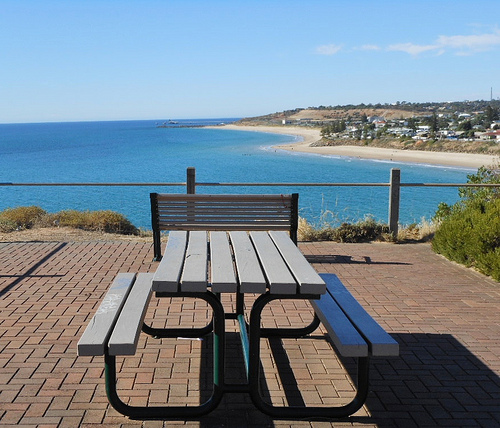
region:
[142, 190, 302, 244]
The bench facing the water.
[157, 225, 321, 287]
The table top of the picnic table.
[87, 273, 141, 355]
The left bench seat of the picnic table.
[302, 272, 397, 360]
The right bench seat of the picnic table.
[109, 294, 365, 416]
The pipes under the picnic table.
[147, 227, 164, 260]
The left leg of the bench.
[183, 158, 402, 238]
The wooden post in front of the bench.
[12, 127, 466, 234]
The water in front of the bench.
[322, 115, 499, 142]
The houses on the right.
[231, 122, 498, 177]
The sand area of the beach.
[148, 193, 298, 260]
wood and metal bench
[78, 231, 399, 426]
wood and metal picnic table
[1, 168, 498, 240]
brown wood fence posts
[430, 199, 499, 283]
green bushes by patio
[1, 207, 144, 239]
green bushes on hill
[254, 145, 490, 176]
wave breaking on shore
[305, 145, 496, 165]
white sand on beach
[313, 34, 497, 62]
white clouds in sky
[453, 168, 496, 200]
tree with green leaves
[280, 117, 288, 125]
white building by beach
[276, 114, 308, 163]
Water washing up on shore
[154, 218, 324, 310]
Gray table on the balcony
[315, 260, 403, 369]
Gray bench on the balcony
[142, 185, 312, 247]
Park Bench on the balcony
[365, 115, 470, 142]
House on the beach front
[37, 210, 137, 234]
Bushes on the ledge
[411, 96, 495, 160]
City view in the distance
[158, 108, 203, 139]
Rocks in the water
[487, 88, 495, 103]
cellphone tower in the city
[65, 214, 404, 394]
Bench and chairs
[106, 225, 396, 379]
A table and bench on the brick floor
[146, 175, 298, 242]
A bench facing view of the ocean.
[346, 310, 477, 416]
Shadow of the bench on ground.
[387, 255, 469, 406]
The ground is made of bricks.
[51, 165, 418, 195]
A rod facing the bench.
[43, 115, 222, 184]
A beautiful beach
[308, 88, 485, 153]
A town sits in the background.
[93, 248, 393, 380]
Two benches and a table.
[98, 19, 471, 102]
The sky has a few clouds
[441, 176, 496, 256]
Bushes growing on the side.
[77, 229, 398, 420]
picnic table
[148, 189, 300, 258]
wood and metal bench overlooking the water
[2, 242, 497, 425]
brick patio with a picnic table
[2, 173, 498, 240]
wood railing by the patio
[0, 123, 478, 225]
clear blue water below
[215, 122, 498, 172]
white sandy beach below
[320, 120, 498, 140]
town beyond the beach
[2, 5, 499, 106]
clear blue sky above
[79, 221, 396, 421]
blown picnic table with a green base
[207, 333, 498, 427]
shadow of picnic table on the ground